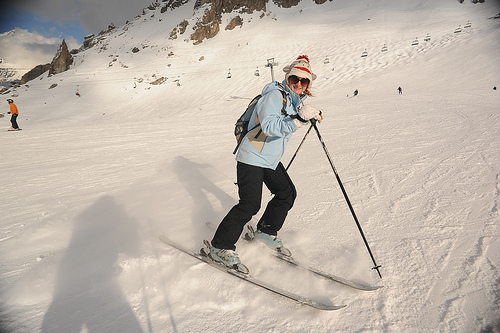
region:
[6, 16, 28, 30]
this is the sky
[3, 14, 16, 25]
the sky is blue in color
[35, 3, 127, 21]
the sky has clouds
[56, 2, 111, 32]
the clouds are grey in color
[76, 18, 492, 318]
this is a mountain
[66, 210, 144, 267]
the ground is full of snow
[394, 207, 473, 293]
the snow is white in color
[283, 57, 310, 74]
this is a cap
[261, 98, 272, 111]
the jacket is blue in color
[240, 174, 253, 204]
the trouser is black in color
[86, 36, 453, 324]
a woman on hill covered with snow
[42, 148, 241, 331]
two shadows cast on the snow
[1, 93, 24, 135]
person wearing an orange top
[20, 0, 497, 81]
a mountain covered with snow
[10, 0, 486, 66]
a rocky mountain covered with snow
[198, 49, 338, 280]
woman wears blue jacket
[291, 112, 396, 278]
two black snow poles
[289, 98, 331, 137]
white snow gloves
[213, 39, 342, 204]
woman carry a backpack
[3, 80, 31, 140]
person ski on the hill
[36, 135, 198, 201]
snow on the mountain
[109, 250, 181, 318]
tracks in the snow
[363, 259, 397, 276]
edge of ski pole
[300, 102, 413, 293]
ski pole in woman's hand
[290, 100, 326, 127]
woman wearing white gloves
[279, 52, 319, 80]
white and red wool cap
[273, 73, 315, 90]
sun glasses on woman's face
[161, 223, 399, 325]
skis on woman's feet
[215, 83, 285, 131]
back pack on woman's back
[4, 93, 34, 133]
man skiing on snow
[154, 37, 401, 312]
A man holding ski poles.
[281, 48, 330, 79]
A fuzzy hat on a person's head.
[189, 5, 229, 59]
A section of snow-less hillside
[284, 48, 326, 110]
a person in glasses.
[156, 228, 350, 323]
a right ski.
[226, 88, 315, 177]
a blue jacket on a girl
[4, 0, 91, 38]
a section of blue sky.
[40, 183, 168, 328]
a shadow in the snow.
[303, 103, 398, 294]
a ski pole in the snow.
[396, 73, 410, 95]
a tree on a snow covered slope ?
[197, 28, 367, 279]
this is a man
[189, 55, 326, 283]
the man is skiing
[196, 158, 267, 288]
the foot of a man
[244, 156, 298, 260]
the foot of a man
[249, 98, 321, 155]
the hand of a man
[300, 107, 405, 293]
this is a ski pole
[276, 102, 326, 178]
this is a ski pole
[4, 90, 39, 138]
this is a man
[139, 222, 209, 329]
this is snow in the ground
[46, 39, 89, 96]
this is a rock